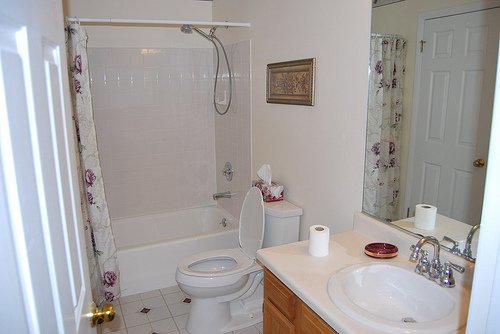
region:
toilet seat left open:
[238, 184, 262, 251]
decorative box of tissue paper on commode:
[251, 163, 283, 200]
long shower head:
[177, 21, 233, 112]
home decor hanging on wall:
[266, 55, 318, 105]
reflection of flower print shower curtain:
[362, 38, 404, 218]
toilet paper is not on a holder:
[308, 225, 331, 256]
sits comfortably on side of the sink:
[307, 222, 331, 255]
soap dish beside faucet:
[364, 238, 400, 259]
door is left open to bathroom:
[3, 2, 115, 332]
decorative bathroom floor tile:
[102, 267, 194, 332]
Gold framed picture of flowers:
[259, 55, 318, 110]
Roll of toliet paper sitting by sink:
[259, 209, 471, 332]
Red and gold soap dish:
[360, 231, 403, 264]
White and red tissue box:
[251, 161, 288, 204]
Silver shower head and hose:
[178, 16, 235, 115]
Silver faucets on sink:
[324, 226, 475, 329]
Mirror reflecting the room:
[363, 3, 493, 268]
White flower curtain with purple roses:
[66, 15, 133, 307]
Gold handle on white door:
[4, 10, 114, 330]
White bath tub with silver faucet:
[111, 185, 243, 292]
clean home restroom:
[0, 2, 478, 329]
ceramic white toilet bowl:
[169, 182, 323, 332]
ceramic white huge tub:
[99, 208, 253, 293]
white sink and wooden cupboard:
[256, 173, 498, 328]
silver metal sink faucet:
[400, 228, 467, 295]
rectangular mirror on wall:
[359, 0, 489, 272]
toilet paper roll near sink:
[299, 218, 330, 259]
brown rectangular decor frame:
[259, 46, 324, 105]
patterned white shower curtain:
[63, 25, 139, 300]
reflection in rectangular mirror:
[362, 0, 485, 267]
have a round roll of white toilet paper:
[308, 223, 329, 259]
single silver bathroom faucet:
[406, 230, 465, 289]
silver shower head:
[177, 22, 234, 115]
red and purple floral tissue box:
[253, 180, 285, 203]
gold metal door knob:
[90, 303, 117, 325]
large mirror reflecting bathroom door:
[360, 1, 499, 262]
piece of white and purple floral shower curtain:
[64, 26, 119, 299]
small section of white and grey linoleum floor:
[115, 296, 182, 332]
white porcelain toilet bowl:
[170, 248, 261, 332]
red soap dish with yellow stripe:
[360, 237, 399, 261]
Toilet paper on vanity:
[311, 205, 341, 279]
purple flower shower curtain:
[76, 25, 131, 310]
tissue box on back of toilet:
[255, 170, 292, 217]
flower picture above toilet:
[259, 45, 329, 131]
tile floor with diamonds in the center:
[121, 291, 191, 330]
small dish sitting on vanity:
[369, 230, 398, 281]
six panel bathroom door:
[8, 35, 118, 330]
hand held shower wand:
[183, 22, 252, 124]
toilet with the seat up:
[183, 185, 264, 327]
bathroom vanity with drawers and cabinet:
[235, 243, 465, 333]